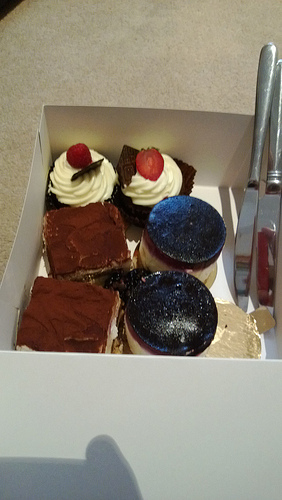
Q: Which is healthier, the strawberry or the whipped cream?
A: The strawberry is healthier than the whipped cream.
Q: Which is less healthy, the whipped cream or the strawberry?
A: The whipped cream is less healthy than the strawberry.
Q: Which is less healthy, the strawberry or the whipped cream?
A: The whipped cream is less healthy than the strawberry.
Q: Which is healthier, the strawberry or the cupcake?
A: The strawberry is healthier than the cupcake.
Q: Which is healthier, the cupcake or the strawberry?
A: The strawberry is healthier than the cupcake.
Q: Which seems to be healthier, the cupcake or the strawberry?
A: The strawberry is healthier than the cupcake.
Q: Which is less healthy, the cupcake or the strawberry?
A: The cupcake is less healthy than the strawberry.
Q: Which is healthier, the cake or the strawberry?
A: The strawberry is healthier than the cake.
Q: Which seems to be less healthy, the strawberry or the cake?
A: The cake is less healthy than the strawberry.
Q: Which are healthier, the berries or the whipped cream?
A: The berries are healthier than the whipped cream.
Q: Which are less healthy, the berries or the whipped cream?
A: The whipped cream are less healthy than the berries.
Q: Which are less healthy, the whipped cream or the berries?
A: The whipped cream are less healthy than the berries.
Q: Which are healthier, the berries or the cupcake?
A: The berries are healthier than the cupcake.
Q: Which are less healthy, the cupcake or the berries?
A: The cupcake are less healthy than the berries.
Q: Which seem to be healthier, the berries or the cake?
A: The berries are healthier than the cake.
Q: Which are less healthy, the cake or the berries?
A: The cake are less healthy than the berries.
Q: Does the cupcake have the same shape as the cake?
A: No, the cupcake is round and the cake is square.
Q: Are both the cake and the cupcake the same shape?
A: No, the cupcake is round and the cake is square.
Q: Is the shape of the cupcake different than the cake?
A: Yes, the cupcake is round and the cake is square.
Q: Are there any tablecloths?
A: No, there are no tablecloths.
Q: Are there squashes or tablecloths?
A: No, there are no tablecloths or squashes.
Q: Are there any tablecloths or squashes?
A: No, there are no tablecloths or squashes.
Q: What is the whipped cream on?
A: The whipped cream is on the cupcake.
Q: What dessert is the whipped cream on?
A: The whipped cream is on the cupcake.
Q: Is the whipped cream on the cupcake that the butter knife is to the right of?
A: Yes, the whipped cream is on the cupcake.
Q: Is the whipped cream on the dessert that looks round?
A: Yes, the whipped cream is on the cupcake.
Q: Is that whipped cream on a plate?
A: No, the whipped cream is on the cupcake.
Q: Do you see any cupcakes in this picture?
A: Yes, there is a cupcake.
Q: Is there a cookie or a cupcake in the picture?
A: Yes, there is a cupcake.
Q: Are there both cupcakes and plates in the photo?
A: No, there is a cupcake but no plates.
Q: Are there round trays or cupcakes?
A: Yes, there is a round cupcake.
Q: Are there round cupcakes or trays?
A: Yes, there is a round cupcake.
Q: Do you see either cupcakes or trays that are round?
A: Yes, the cupcake is round.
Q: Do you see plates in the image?
A: No, there are no plates.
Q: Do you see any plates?
A: No, there are no plates.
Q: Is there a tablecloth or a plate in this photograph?
A: No, there are no plates or tablecloths.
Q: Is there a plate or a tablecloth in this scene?
A: No, there are no plates or tablecloths.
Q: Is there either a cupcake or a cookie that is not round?
A: No, there is a cupcake but it is round.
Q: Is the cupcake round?
A: Yes, the cupcake is round.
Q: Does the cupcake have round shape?
A: Yes, the cupcake is round.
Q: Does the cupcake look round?
A: Yes, the cupcake is round.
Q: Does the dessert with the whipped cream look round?
A: Yes, the cupcake is round.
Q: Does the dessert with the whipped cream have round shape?
A: Yes, the cupcake is round.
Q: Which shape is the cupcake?
A: The cupcake is round.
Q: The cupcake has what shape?
A: The cupcake is round.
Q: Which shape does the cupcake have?
A: The cupcake has round shape.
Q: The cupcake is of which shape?
A: The cupcake is round.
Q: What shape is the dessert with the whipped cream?
A: The cupcake is round.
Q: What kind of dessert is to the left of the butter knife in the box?
A: The dessert is a cupcake.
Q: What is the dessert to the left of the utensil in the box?
A: The dessert is a cupcake.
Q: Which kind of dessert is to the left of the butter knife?
A: The dessert is a cupcake.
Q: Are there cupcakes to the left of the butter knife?
A: Yes, there is a cupcake to the left of the butter knife.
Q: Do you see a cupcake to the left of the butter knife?
A: Yes, there is a cupcake to the left of the butter knife.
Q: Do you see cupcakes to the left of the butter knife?
A: Yes, there is a cupcake to the left of the butter knife.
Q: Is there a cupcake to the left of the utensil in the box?
A: Yes, there is a cupcake to the left of the butter knife.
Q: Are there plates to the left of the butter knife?
A: No, there is a cupcake to the left of the butter knife.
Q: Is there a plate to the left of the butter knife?
A: No, there is a cupcake to the left of the butter knife.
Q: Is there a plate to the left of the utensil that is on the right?
A: No, there is a cupcake to the left of the butter knife.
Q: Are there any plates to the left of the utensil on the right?
A: No, there is a cupcake to the left of the butter knife.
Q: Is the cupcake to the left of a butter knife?
A: Yes, the cupcake is to the left of a butter knife.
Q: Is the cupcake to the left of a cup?
A: No, the cupcake is to the left of a butter knife.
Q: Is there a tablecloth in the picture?
A: No, there are no tablecloths.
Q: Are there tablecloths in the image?
A: No, there are no tablecloths.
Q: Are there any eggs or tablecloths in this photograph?
A: No, there are no tablecloths or eggs.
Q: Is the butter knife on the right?
A: Yes, the butter knife is on the right of the image.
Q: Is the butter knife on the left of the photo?
A: No, the butter knife is on the right of the image.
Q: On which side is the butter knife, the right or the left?
A: The butter knife is on the right of the image.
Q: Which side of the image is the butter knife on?
A: The butter knife is on the right of the image.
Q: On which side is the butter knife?
A: The butter knife is on the right of the image.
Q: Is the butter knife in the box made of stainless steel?
A: Yes, the butter knife is made of stainless steel.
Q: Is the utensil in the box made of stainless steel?
A: Yes, the butter knife is made of stainless steel.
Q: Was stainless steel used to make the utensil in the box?
A: Yes, the butter knife is made of stainless steel.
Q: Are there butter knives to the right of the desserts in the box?
A: Yes, there is a butter knife to the right of the desserts.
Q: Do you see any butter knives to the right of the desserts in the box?
A: Yes, there is a butter knife to the right of the desserts.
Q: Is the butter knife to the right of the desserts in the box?
A: Yes, the butter knife is to the right of the desserts.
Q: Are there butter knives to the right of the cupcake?
A: Yes, there is a butter knife to the right of the cupcake.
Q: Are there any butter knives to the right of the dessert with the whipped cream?
A: Yes, there is a butter knife to the right of the cupcake.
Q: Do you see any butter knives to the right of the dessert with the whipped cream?
A: Yes, there is a butter knife to the right of the cupcake.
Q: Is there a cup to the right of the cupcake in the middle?
A: No, there is a butter knife to the right of the cupcake.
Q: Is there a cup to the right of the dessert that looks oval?
A: No, there is a butter knife to the right of the cupcake.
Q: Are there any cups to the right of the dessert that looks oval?
A: No, there is a butter knife to the right of the cupcake.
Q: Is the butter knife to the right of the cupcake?
A: Yes, the butter knife is to the right of the cupcake.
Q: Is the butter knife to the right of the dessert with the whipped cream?
A: Yes, the butter knife is to the right of the cupcake.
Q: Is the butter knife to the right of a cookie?
A: No, the butter knife is to the right of the cupcake.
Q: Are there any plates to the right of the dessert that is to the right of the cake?
A: No, there is a butter knife to the right of the dessert.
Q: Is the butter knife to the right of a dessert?
A: Yes, the butter knife is to the right of a dessert.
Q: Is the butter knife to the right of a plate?
A: No, the butter knife is to the right of a dessert.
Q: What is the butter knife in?
A: The butter knife is in the box.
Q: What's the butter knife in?
A: The butter knife is in the box.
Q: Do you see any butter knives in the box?
A: Yes, there is a butter knife in the box.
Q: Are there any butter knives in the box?
A: Yes, there is a butter knife in the box.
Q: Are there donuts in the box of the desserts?
A: No, there is a butter knife in the box.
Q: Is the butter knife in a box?
A: Yes, the butter knife is in a box.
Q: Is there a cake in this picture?
A: Yes, there is a cake.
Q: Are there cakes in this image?
A: Yes, there is a cake.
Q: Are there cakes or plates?
A: Yes, there is a cake.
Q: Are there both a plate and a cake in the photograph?
A: No, there is a cake but no plates.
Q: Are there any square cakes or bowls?
A: Yes, there is a square cake.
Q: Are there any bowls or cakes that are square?
A: Yes, the cake is square.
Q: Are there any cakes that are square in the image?
A: Yes, there is a square cake.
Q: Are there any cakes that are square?
A: Yes, there is a cake that is square.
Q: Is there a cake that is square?
A: Yes, there is a cake that is square.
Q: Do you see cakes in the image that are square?
A: Yes, there is a cake that is square.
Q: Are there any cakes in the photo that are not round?
A: Yes, there is a square cake.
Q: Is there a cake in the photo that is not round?
A: Yes, there is a square cake.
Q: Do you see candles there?
A: No, there are no candles.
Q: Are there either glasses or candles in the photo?
A: No, there are no candles or glasses.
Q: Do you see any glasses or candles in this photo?
A: No, there are no candles or glasses.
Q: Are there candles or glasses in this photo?
A: No, there are no candles or glasses.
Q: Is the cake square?
A: Yes, the cake is square.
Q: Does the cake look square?
A: Yes, the cake is square.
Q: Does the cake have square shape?
A: Yes, the cake is square.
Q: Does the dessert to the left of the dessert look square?
A: Yes, the cake is square.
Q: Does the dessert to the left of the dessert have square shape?
A: Yes, the cake is square.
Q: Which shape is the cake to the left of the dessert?
A: The cake is square.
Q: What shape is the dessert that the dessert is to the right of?
A: The cake is square.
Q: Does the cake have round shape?
A: No, the cake is square.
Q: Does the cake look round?
A: No, the cake is square.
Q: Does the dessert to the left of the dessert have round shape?
A: No, the cake is square.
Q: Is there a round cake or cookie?
A: No, there is a cake but it is square.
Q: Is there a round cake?
A: No, there is a cake but it is square.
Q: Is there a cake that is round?
A: No, there is a cake but it is square.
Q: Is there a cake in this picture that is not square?
A: No, there is a cake but it is square.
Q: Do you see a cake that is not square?
A: No, there is a cake but it is square.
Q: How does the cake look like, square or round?
A: The cake is square.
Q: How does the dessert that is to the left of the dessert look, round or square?
A: The cake is square.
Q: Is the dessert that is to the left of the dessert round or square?
A: The cake is square.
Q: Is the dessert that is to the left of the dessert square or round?
A: The cake is square.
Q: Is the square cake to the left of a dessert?
A: Yes, the cake is to the left of a dessert.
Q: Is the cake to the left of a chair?
A: No, the cake is to the left of a dessert.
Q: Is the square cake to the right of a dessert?
A: No, the cake is to the left of a dessert.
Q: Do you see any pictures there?
A: No, there are no pictures.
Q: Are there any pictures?
A: No, there are no pictures.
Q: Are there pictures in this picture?
A: No, there are no pictures.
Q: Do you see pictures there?
A: No, there are no pictures.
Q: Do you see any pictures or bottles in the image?
A: No, there are no pictures or bottles.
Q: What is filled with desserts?
A: The box is filled with desserts.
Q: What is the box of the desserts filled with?
A: The box is filled with desserts.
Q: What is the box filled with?
A: The box is filled with desserts.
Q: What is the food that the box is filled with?
A: The food is desserts.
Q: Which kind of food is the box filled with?
A: The box is filled with desserts.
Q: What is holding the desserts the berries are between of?
A: The box is holding the desserts.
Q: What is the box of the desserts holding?
A: The box is holding the desserts.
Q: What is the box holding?
A: The box is holding the desserts.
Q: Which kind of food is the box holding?
A: The box is holding the desserts.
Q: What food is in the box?
A: The food is desserts.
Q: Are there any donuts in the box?
A: No, there are desserts in the box.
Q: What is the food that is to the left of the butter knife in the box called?
A: The food is desserts.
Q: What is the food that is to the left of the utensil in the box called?
A: The food is desserts.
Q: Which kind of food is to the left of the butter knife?
A: The food is desserts.